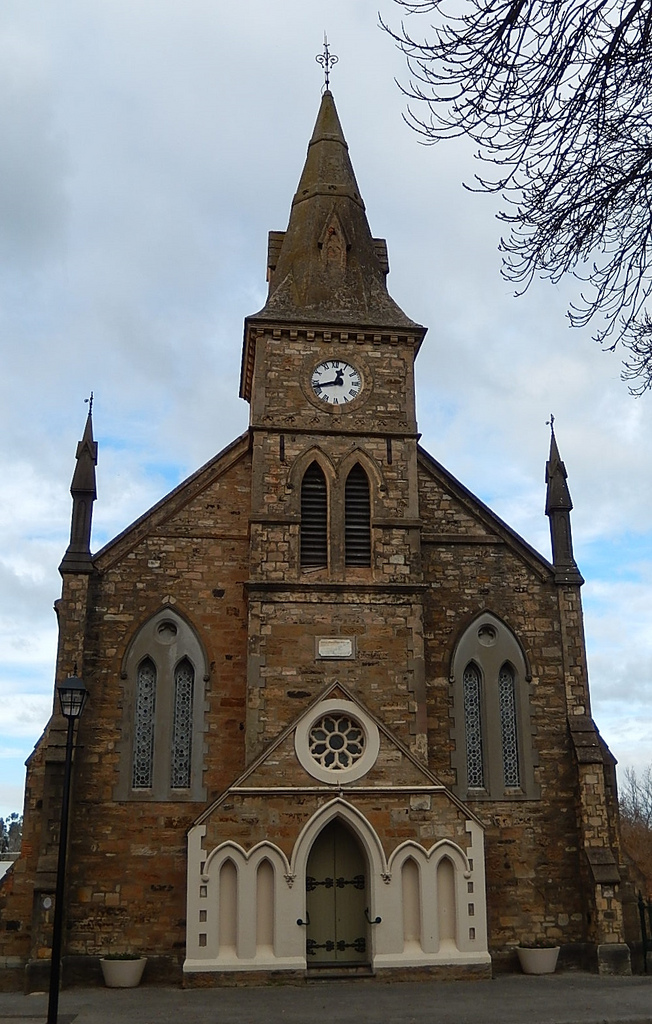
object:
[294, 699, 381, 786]
circle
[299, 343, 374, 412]
clock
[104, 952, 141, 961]
plant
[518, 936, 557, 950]
plant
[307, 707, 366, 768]
decoration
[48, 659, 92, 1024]
lamp post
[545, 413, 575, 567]
decorative turrent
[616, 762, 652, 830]
leaves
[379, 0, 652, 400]
leaves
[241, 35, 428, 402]
steeple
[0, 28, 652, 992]
building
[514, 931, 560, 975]
planter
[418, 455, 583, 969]
wall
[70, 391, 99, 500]
top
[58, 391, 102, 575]
pole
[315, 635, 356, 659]
plaque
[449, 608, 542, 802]
window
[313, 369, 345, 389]
hands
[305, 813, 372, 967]
door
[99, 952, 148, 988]
fern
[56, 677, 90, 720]
light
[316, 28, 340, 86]
top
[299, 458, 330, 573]
shutters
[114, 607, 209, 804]
window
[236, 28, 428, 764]
tower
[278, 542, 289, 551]
brick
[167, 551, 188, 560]
brick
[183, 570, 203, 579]
brick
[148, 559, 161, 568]
brick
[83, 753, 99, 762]
brick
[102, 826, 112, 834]
brick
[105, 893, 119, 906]
brick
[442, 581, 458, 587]
brick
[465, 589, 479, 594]
brick